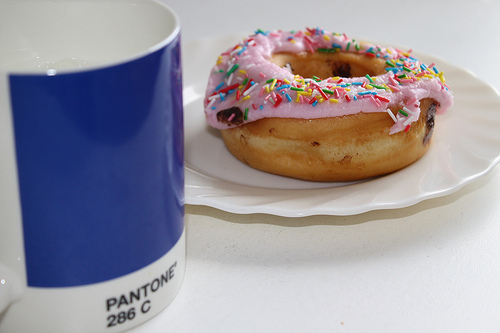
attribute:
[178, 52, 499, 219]
plate — white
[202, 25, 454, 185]
donut — for morning, colorful, jelly filled, sweet, jelly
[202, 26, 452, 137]
frosting — pink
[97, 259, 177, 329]
writing — black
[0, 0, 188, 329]
mug — blue, white, black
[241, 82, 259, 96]
sprinkle — white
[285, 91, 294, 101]
sprinkle — blue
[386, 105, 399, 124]
sprinkle — white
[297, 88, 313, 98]
sprinkle — yellow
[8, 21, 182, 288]
square — blue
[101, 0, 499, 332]
table — white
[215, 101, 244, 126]
smear — chocolate